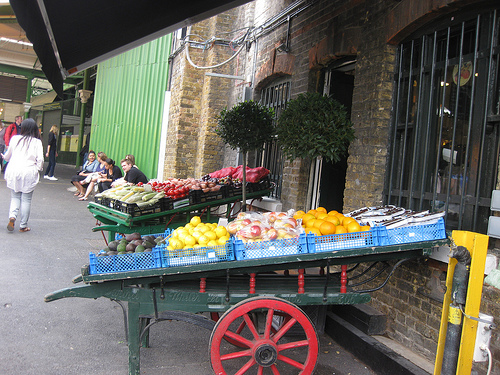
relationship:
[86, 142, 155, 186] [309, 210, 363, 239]
people near oranges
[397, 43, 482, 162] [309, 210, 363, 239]
bars near oranges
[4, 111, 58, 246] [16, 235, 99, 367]
girl on street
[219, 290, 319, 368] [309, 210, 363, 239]
wheel near oranges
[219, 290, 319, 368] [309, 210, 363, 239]
wheel below oranges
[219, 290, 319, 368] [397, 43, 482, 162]
wheel below bars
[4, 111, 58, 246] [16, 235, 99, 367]
girl in street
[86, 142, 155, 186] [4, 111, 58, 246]
people near girl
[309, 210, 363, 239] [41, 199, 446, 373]
oranges in fruit cart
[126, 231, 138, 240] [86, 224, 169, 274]
avocado in basket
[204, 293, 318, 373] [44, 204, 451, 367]
wheel on cart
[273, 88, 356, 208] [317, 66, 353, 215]
plant sitting near doorway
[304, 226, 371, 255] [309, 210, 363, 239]
crate of oranges